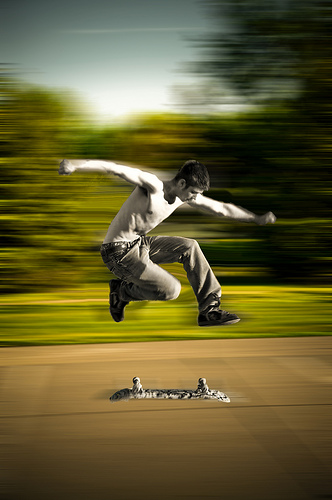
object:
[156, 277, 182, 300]
knee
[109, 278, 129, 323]
shoe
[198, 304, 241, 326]
shoe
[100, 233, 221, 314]
jeans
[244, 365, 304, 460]
ground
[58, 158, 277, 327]
boy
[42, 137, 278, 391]
tricks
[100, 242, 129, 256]
belt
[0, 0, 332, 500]
background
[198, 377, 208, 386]
wheels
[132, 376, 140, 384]
wheels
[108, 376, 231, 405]
skate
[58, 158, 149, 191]
arm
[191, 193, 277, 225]
arm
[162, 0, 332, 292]
trees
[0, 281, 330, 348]
grass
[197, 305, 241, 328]
sneaker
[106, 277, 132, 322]
sneaker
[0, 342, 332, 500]
dirt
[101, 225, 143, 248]
waist